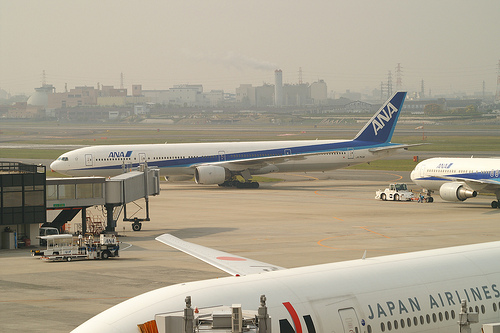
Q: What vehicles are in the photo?
A: Airplanes.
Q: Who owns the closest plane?
A: Japan airlines.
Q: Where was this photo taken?
A: At the airport.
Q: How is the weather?
A: Gloomy.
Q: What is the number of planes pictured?
A: Three.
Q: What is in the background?
A: Group of buildings.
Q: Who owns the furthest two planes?
A: Ana.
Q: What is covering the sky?
A: Clouds.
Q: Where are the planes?
A: On the tarmac.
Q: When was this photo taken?
A: In the daytime.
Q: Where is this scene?
A: The airport.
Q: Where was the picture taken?
A: An airport.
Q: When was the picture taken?
A: Daytime.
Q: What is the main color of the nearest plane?
A: White.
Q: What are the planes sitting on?
A: Tarmac.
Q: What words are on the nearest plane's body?
A: JAPAN AIRLINES.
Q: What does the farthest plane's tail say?
A: ANA.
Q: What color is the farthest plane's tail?
A: Blue.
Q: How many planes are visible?
A: Three.